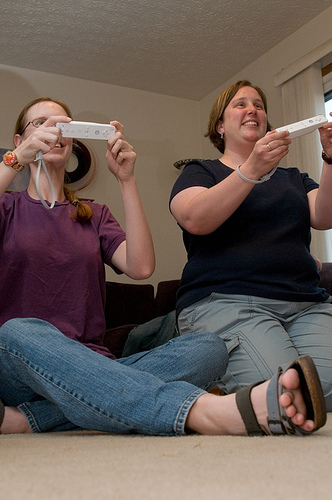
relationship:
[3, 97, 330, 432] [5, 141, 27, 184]
woman has watch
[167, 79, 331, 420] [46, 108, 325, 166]
woman hold controllers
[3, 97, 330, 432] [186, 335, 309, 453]
woman wears sandals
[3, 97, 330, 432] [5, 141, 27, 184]
woman wears watch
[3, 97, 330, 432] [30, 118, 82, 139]
woman has glasses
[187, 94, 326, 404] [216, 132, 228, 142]
woman wears earring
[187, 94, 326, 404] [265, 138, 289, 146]
woman wears ring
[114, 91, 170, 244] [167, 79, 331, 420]
wall behind woman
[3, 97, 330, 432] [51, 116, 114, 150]
woman holds controller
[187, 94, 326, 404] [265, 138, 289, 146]
woman has ring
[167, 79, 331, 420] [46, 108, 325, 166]
woman holding controllers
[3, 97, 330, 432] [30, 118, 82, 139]
woman wears glasses